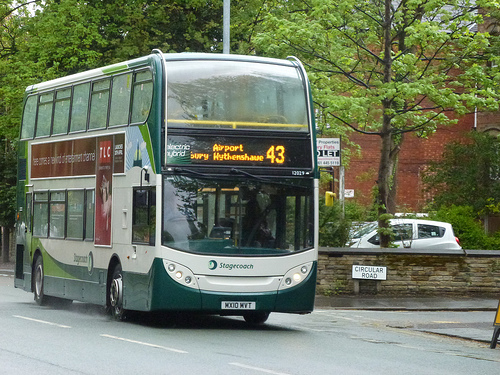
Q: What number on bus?
A: Forty three.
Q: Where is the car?
A: Parked on street.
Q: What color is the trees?
A: Green.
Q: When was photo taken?
A: Daytime.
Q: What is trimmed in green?
A: Bus.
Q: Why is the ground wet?
A: Raining.